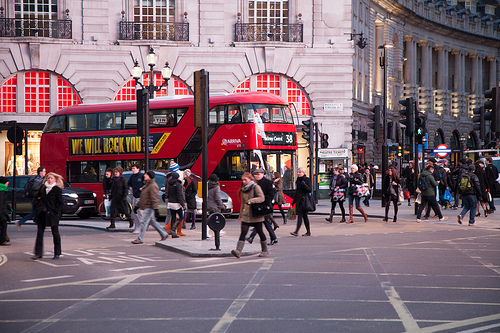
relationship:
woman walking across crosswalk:
[234, 170, 270, 259] [6, 242, 180, 272]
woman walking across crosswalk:
[26, 168, 66, 259] [7, 240, 181, 267]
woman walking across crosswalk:
[340, 160, 370, 223] [226, 210, 406, 250]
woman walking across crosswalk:
[380, 163, 407, 225] [12, 235, 483, 285]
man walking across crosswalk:
[129, 170, 170, 244] [0, 222, 194, 284]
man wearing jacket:
[129, 170, 170, 244] [131, 179, 162, 209]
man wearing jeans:
[131, 163, 167, 243] [131, 209, 168, 245]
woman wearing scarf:
[232, 172, 270, 260] [220, 169, 277, 199]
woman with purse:
[232, 172, 270, 260] [247, 200, 272, 216]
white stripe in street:
[383, 280, 423, 331] [0, 214, 498, 331]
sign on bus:
[72, 133, 168, 155] [29, 92, 300, 225]